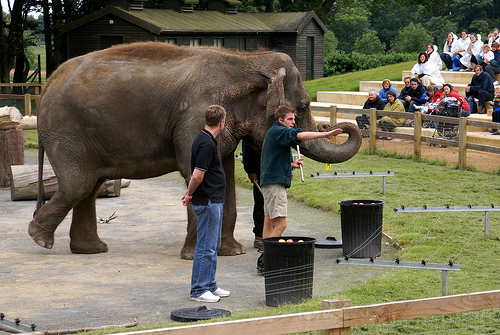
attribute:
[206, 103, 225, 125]
hair — black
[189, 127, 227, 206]
shirt — black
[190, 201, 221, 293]
jeans — blue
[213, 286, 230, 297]
sneaker — white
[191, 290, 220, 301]
sneaker — white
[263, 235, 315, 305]
garbage can — black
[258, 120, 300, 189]
sweater — green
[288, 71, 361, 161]
trunk — curled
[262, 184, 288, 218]
shorts — beige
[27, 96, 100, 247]
leg — raised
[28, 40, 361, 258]
elephant —  hairy 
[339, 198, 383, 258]
barrel — black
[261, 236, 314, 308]
barrel — black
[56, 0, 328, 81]
cabin — brown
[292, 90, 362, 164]
trunk — curled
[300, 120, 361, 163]
trunk —  elephant's,  curled up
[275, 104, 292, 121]
hair —  brown,  Man's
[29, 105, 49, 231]
tail — long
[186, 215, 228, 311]
jeans — blue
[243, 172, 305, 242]
shorts — khaki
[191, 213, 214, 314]
jeans — blue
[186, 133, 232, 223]
polo shirt — black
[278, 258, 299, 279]
can —  large and black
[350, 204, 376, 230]
can —  large and black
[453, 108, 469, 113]
shirt — red